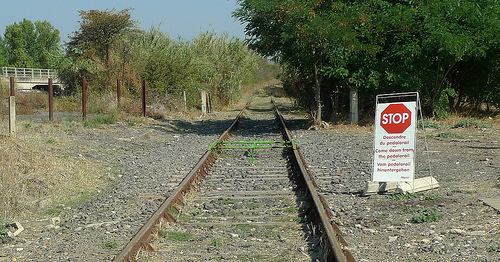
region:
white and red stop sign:
[374, 90, 436, 202]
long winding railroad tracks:
[108, 34, 355, 260]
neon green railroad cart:
[193, 132, 305, 174]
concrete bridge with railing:
[2, 57, 83, 113]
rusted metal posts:
[3, 72, 164, 123]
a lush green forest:
[243, 1, 498, 129]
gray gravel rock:
[80, 121, 498, 260]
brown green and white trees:
[65, 7, 251, 103]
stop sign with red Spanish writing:
[370, 92, 434, 201]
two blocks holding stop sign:
[363, 165, 445, 209]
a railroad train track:
[112, 80, 358, 259]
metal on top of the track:
[111, 87, 345, 260]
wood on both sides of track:
[110, 84, 363, 260]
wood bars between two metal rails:
[124, 80, 338, 259]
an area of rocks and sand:
[3, 112, 498, 257]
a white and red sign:
[370, 98, 418, 187]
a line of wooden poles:
[1, 72, 151, 130]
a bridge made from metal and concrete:
[0, 62, 75, 93]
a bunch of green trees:
[0, 0, 499, 129]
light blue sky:
[0, 0, 285, 67]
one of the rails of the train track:
[270, 100, 342, 260]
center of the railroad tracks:
[207, 124, 277, 259]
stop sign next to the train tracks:
[381, 109, 412, 136]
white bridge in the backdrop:
[5, 65, 94, 92]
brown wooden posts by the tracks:
[11, 74, 162, 118]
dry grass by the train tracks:
[0, 140, 93, 214]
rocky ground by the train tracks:
[310, 134, 367, 185]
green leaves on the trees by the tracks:
[247, 5, 481, 84]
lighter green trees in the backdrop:
[130, 36, 257, 89]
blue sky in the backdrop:
[32, 5, 242, 40]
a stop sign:
[371, 93, 426, 137]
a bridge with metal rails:
[3, 55, 83, 110]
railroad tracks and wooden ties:
[187, 102, 340, 233]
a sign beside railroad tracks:
[273, 7, 450, 218]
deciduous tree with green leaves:
[306, 8, 384, 114]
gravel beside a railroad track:
[124, 131, 206, 214]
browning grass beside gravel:
[43, 133, 127, 225]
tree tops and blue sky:
[53, 1, 256, 65]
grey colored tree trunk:
[342, 63, 370, 130]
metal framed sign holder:
[355, 88, 445, 196]